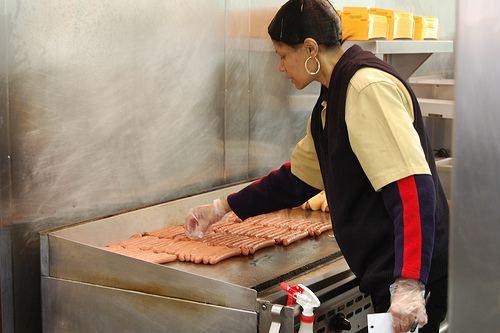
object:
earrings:
[304, 56, 322, 77]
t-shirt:
[289, 66, 434, 194]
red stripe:
[396, 175, 423, 281]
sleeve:
[343, 70, 437, 286]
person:
[180, 0, 452, 333]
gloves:
[183, 196, 236, 240]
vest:
[308, 43, 450, 295]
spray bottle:
[278, 281, 322, 333]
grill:
[36, 177, 376, 333]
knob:
[328, 311, 353, 333]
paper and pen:
[365, 290, 434, 333]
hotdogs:
[207, 246, 242, 266]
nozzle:
[279, 281, 291, 292]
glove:
[386, 276, 430, 333]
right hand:
[182, 203, 225, 240]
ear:
[303, 37, 320, 59]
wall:
[0, 0, 251, 234]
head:
[265, 0, 355, 92]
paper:
[365, 312, 421, 333]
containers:
[332, 6, 391, 41]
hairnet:
[266, 0, 344, 45]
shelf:
[340, 38, 455, 56]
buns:
[320, 199, 330, 213]